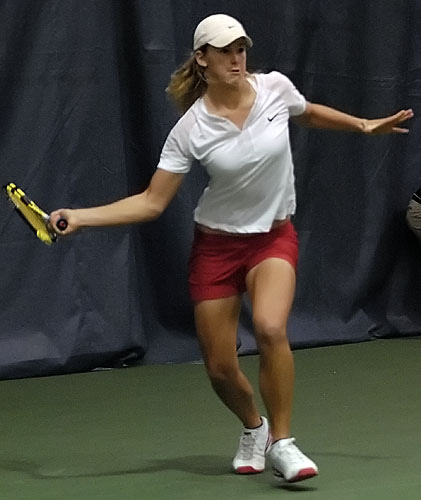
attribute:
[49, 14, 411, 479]
woman — tennis playing, wearing white, white wearing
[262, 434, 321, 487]
shoe — red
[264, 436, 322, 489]
shoe — white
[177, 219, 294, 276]
shorts — red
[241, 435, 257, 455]
laces — white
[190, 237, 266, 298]
shorts — red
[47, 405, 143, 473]
ground — green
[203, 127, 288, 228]
shirt — white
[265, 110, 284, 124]
logo — black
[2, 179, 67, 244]
tennis racquet — black, yellow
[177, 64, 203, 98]
hair — blonde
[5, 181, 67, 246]
racquet — black,  yellow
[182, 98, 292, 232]
shirt — white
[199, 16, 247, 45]
hat — white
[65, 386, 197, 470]
tennis court — green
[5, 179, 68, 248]
racket — black, yellow